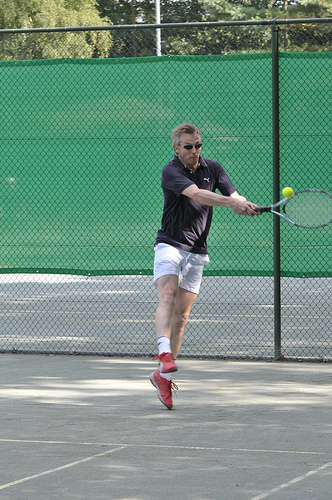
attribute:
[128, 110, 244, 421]
man wearing red — white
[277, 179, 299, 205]
tennis ball — yellow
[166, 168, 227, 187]
polo shirt — black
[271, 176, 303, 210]
bright green ball — yellow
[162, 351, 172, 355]
sole on sneaker — white, red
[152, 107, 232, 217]
man wearing glasses — black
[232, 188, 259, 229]
two hand backhand — two-handed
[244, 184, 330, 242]
racket — grey, black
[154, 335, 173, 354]
socks — white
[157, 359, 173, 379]
socks — white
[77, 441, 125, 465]
line — white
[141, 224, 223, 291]
shorts — white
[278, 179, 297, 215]
ball — yellow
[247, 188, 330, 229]
racquet — black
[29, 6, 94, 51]
tree — large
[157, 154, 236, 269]
shirt — blue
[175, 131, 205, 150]
glasses — dark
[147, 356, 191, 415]
shoes — red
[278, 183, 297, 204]
ball — yellow, round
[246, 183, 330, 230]
rack — silver, black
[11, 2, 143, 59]
trees — green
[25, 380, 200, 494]
court — green